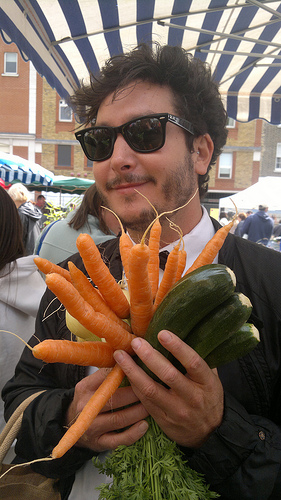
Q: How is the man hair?
A: Brown.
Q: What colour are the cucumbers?
A: Green.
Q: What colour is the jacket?
A: Black.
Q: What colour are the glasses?
A: Black.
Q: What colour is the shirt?
A: White.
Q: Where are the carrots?
A: In the hand.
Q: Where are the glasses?
A: On the man.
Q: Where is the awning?
A: Above the people.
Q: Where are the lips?
A: On the man.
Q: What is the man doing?
A: Holding vegetables.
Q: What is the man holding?
A: Vegetables.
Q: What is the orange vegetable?
A: Carrots.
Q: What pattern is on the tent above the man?
A: Stripes.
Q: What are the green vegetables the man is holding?
A: Zucchini.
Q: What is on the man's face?
A: Sunglasses.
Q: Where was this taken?
A: An outside market.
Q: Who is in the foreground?
A: A man.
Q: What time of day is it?
A: Daytime.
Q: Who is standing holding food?
A: A man.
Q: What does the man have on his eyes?
A: Sunglasses.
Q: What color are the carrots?
A: Orange.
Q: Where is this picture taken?
A: At an outdoor flea market.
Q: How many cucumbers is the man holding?
A: Three.